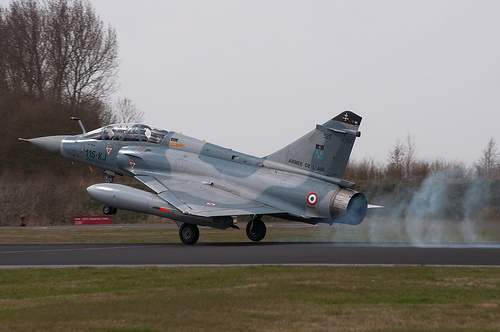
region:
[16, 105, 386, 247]
Fighter jet on runway.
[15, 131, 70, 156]
Nose of the airplane.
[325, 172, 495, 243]
Exhaust coming out of airplane.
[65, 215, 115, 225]
Red small structure on runway.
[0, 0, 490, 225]
Trees in the background.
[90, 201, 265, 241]
Wheels on the airplane.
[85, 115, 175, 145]
Cockpit of the airplane.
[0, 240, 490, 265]
Runway of the airport.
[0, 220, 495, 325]
Grass around the runway.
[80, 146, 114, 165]
Identifying marks on plane.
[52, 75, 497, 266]
one military jet on runway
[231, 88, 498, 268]
plane blowing smoke in photo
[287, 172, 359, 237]
red white blue target on back of plane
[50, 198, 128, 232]
red sign with white lettering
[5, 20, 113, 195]
large tree in background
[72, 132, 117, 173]
black writing on jet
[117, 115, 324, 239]
green and tan plane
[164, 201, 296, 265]
two wheels on pavement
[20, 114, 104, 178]
long pointed nose on plane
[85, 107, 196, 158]
one window on fighter jet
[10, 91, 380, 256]
tiny gray plane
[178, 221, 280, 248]
two circular black wheels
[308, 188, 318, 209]
red, white, and blue circle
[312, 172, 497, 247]
smoking coming out of the back of the plane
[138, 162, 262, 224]
triangle shaped wing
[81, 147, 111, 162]
black lettering that says "115-KJ"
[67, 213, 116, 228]
red sign with light lettering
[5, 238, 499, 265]
runway made of asphalt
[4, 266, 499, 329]
green and brown grass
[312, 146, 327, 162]
blue box with three yellow stars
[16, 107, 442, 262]
military jet about to take off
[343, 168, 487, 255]
smoke from military jet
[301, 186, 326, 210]
red, white and blue bullseye painted on jet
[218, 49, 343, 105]
grey clear sky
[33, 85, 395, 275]
military jet on runway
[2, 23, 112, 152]
tall trees with no leaves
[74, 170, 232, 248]
grey missile attached to military jet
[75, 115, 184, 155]
glass covering cockpit of jet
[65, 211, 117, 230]
red sign with white lettering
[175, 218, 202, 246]
a black tire on the plane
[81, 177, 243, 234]
a missile on the plane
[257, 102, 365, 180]
the tail of a plane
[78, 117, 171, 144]
the cockpit of a plane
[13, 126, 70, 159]
the nose of a plane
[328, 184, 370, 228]
the afterburner on the plane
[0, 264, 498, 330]
a green grassy field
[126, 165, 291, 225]
a wing on the plan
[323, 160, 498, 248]
smoke behind the plane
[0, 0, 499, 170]
a gray sky overhead